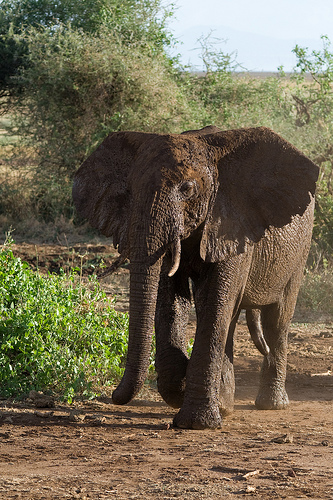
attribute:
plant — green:
[0, 230, 130, 400]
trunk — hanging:
[110, 223, 167, 408]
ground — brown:
[3, 431, 332, 496]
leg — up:
[153, 353, 191, 410]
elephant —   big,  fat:
[69, 76, 332, 359]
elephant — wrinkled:
[82, 127, 328, 459]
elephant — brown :
[86, 122, 254, 357]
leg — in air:
[164, 292, 191, 406]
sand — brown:
[0, 405, 260, 498]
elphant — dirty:
[69, 123, 317, 430]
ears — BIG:
[219, 123, 307, 219]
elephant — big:
[47, 84, 330, 444]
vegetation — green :
[12, 235, 187, 438]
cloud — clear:
[206, 9, 311, 63]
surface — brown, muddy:
[250, 403, 308, 491]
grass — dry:
[3, 130, 127, 254]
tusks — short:
[103, 235, 189, 273]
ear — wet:
[66, 137, 155, 252]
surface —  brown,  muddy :
[6, 426, 329, 498]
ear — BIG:
[65, 132, 143, 230]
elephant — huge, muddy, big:
[63, 112, 325, 434]